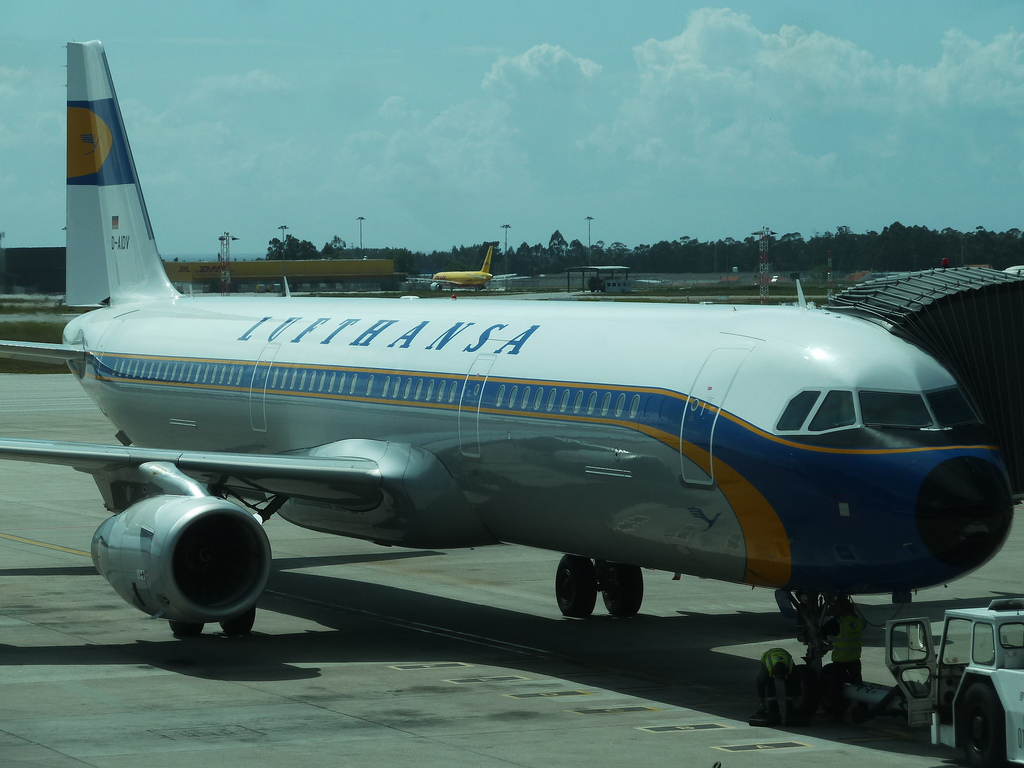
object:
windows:
[770, 388, 978, 434]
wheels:
[555, 554, 643, 615]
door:
[681, 332, 766, 484]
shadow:
[0, 546, 1024, 768]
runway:
[0, 345, 1023, 762]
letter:
[495, 325, 541, 355]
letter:
[110, 236, 127, 249]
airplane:
[0, 39, 1011, 642]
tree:
[681, 235, 694, 267]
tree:
[290, 241, 322, 292]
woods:
[191, 222, 1024, 286]